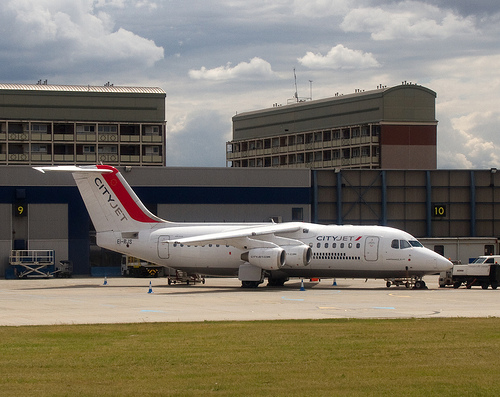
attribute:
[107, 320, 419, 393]
grass — green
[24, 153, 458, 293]
jet — white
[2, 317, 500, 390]
field — grassy, greenish brown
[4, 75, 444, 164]
buildings — tall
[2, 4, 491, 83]
sky — gray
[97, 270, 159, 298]
cone — blue, white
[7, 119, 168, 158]
windows — small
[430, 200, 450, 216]
sign — black, yellow